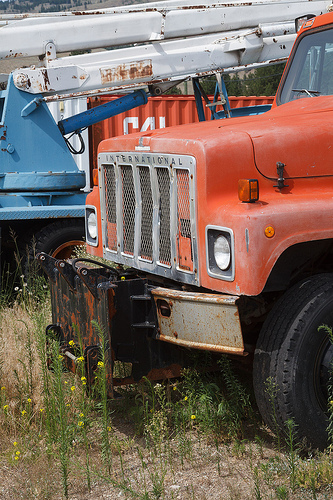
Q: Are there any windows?
A: Yes, there is a window.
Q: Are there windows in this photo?
A: Yes, there is a window.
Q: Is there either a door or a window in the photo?
A: Yes, there is a window.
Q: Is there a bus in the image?
A: No, there are no buses.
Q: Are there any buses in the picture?
A: No, there are no buses.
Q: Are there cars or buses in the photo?
A: No, there are no buses or cars.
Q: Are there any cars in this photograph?
A: No, there are no cars.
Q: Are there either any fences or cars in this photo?
A: No, there are no cars or fences.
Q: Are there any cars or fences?
A: No, there are no cars or fences.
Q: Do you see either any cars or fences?
A: No, there are no cars or fences.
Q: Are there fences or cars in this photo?
A: No, there are no cars or fences.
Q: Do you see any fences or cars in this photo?
A: No, there are no cars or fences.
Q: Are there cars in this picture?
A: No, there are no cars.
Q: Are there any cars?
A: No, there are no cars.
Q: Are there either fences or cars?
A: No, there are no cars or fences.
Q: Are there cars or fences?
A: No, there are no cars or fences.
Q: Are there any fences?
A: No, there are no fences.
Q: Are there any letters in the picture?
A: Yes, there are letters.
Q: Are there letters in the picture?
A: Yes, there are letters.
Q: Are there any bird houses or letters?
A: Yes, there are letters.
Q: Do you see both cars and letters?
A: No, there are letters but no cars.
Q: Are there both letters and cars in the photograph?
A: No, there are letters but no cars.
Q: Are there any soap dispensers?
A: No, there are no soap dispensers.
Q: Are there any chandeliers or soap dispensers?
A: No, there are no soap dispensers or chandeliers.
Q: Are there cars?
A: No, there are no cars.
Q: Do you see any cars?
A: No, there are no cars.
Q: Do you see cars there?
A: No, there are no cars.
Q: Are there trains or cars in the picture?
A: No, there are no cars or trains.